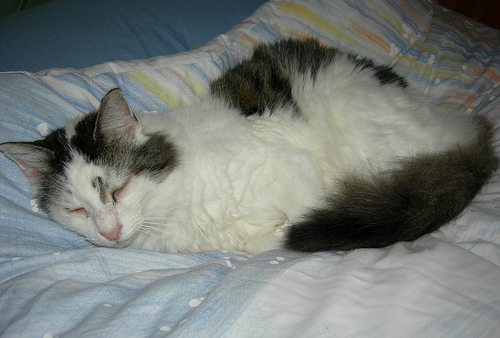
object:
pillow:
[371, 24, 455, 63]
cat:
[0, 36, 500, 254]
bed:
[0, 0, 500, 337]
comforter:
[0, 0, 500, 337]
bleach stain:
[390, 26, 483, 104]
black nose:
[98, 223, 134, 243]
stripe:
[56, 120, 104, 165]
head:
[15, 106, 182, 243]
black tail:
[283, 113, 499, 253]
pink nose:
[90, 216, 135, 224]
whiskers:
[147, 213, 194, 241]